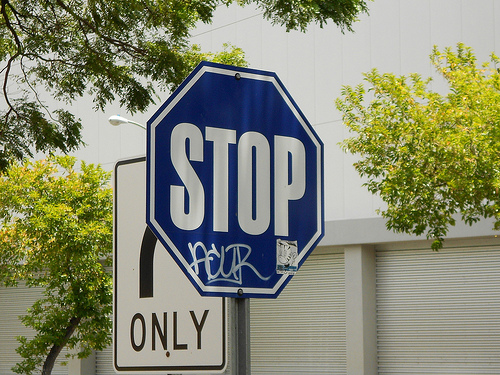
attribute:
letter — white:
[271, 133, 308, 235]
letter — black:
[131, 312, 146, 351]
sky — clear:
[0, 1, 498, 224]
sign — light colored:
[132, 57, 329, 307]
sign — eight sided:
[123, 32, 365, 318]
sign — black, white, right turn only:
[113, 155, 226, 372]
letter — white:
[169, 122, 205, 230]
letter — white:
[205, 125, 236, 234]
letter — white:
[237, 130, 271, 235]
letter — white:
[274, 135, 302, 235]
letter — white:
[185, 241, 272, 286]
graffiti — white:
[183, 235, 273, 290]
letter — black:
[188, 308, 210, 350]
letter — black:
[172, 310, 188, 350]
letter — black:
[150, 310, 168, 350]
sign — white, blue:
[144, 60, 323, 297]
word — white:
[123, 305, 209, 354]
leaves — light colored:
[331, 39, 498, 254]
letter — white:
[162, 117, 202, 244]